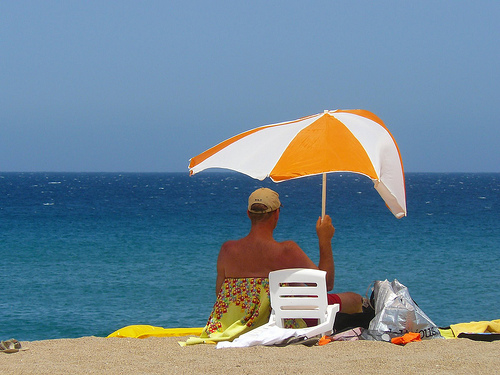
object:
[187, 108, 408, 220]
umbrella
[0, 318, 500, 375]
beach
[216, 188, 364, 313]
man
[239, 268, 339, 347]
beach chair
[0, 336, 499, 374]
sand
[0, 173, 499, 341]
water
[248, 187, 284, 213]
hat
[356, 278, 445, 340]
bag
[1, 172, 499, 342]
ocean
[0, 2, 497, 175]
sky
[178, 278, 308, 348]
beach towel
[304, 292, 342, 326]
shorts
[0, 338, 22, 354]
shoe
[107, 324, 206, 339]
beach toy